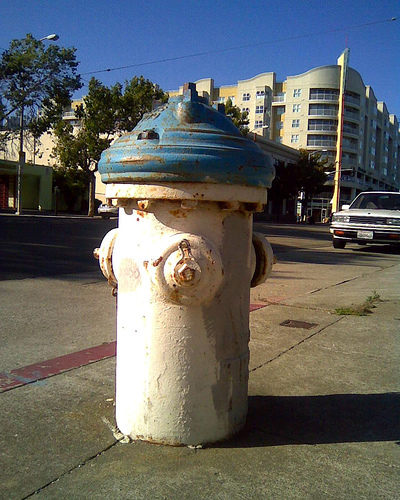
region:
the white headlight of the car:
[334, 213, 351, 221]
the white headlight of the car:
[384, 216, 399, 225]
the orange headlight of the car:
[333, 227, 343, 237]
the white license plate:
[355, 231, 374, 240]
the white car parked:
[329, 189, 398, 246]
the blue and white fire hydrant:
[79, 76, 279, 446]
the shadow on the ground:
[206, 392, 398, 445]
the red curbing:
[1, 295, 267, 403]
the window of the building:
[292, 88, 303, 98]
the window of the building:
[292, 101, 301, 112]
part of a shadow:
[268, 426, 274, 442]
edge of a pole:
[181, 361, 189, 372]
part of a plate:
[319, 329, 321, 333]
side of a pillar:
[211, 455, 214, 459]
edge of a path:
[276, 428, 277, 436]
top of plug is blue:
[126, 80, 239, 182]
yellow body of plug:
[112, 195, 233, 420]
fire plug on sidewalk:
[83, 94, 248, 442]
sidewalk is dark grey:
[252, 292, 342, 433]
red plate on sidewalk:
[10, 316, 271, 395]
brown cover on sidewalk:
[282, 314, 311, 331]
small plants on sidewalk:
[314, 289, 390, 323]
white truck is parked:
[344, 193, 388, 243]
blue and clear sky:
[190, 14, 235, 61]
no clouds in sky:
[190, 1, 262, 61]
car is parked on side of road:
[332, 184, 396, 248]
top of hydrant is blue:
[85, 80, 274, 188]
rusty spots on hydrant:
[92, 80, 272, 445]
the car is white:
[325, 176, 394, 260]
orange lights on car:
[328, 224, 396, 240]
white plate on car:
[357, 228, 375, 242]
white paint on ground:
[99, 413, 130, 447]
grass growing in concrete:
[330, 286, 384, 324]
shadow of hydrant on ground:
[195, 395, 398, 450]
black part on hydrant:
[140, 126, 153, 142]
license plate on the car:
[356, 230, 372, 239]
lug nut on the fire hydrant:
[170, 258, 199, 289]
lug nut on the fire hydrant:
[178, 82, 206, 99]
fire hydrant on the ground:
[94, 82, 281, 451]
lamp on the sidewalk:
[11, 27, 64, 221]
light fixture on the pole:
[46, 33, 65, 45]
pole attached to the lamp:
[12, 50, 23, 219]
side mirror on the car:
[340, 200, 348, 208]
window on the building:
[293, 86, 302, 96]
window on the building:
[291, 117, 301, 129]